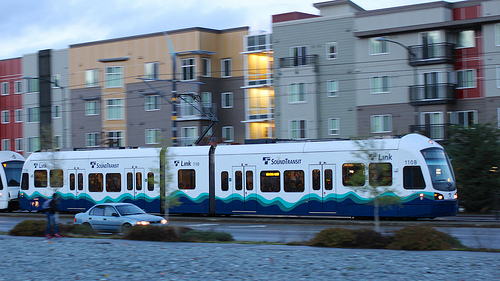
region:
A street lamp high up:
[372, 38, 380, 42]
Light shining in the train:
[266, 173, 278, 175]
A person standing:
[49, 196, 57, 238]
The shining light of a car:
[140, 221, 146, 224]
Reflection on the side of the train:
[30, 199, 37, 206]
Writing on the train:
[274, 159, 301, 164]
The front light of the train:
[438, 193, 441, 199]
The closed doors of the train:
[312, 193, 334, 210]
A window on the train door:
[314, 173, 318, 185]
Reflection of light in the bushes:
[491, 166, 497, 171]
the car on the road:
[72, 202, 168, 234]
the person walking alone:
[43, 191, 61, 238]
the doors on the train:
[310, 163, 336, 214]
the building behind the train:
[0, 0, 499, 147]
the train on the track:
[0, 132, 459, 221]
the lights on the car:
[136, 219, 166, 224]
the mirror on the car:
[110, 211, 117, 217]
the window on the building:
[369, 75, 389, 94]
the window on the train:
[87, 173, 102, 191]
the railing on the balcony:
[406, 83, 454, 100]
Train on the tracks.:
[3, 126, 465, 218]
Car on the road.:
[70, 199, 166, 234]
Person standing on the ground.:
[44, 192, 64, 239]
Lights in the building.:
[245, 51, 275, 142]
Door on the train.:
[228, 161, 260, 216]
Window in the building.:
[139, 89, 163, 114]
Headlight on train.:
[428, 188, 460, 203]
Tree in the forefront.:
[340, 131, 400, 237]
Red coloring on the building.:
[450, 3, 485, 100]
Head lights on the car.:
[134, 214, 171, 229]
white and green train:
[20, 132, 462, 221]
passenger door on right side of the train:
[306, 164, 334, 201]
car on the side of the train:
[75, 197, 170, 228]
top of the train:
[26, 130, 441, 160]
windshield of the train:
[418, 145, 458, 191]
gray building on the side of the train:
[275, 5, 450, 144]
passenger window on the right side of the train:
[283, 167, 306, 191]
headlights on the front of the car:
[136, 219, 166, 223]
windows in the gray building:
[368, 27, 397, 94]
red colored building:
[0, 56, 24, 153]